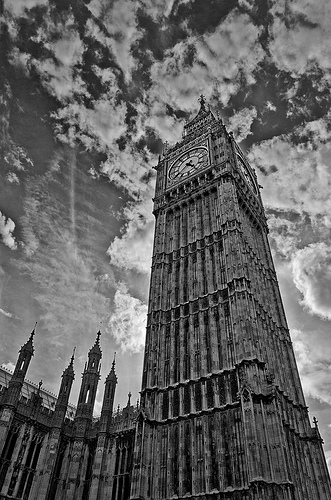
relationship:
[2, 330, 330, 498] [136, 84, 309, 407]
building attached tower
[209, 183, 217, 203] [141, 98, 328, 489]
arch inspired arches on a tower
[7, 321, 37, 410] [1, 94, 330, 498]
spire on a building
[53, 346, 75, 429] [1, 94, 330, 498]
spire on a building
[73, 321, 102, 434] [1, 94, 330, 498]
spire on a building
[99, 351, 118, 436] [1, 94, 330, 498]
spire on a building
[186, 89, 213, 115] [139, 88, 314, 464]
spire on a clock tower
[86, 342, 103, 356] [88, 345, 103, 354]
cap and spire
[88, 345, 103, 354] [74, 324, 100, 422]
spire on top of corner tower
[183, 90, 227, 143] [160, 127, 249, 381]
steeple of top of tower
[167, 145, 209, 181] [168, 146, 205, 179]
clock with numerals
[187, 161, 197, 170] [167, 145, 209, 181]
hour handle on clock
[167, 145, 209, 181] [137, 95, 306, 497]
clock on top of building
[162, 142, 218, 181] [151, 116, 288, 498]
clock in front of tower